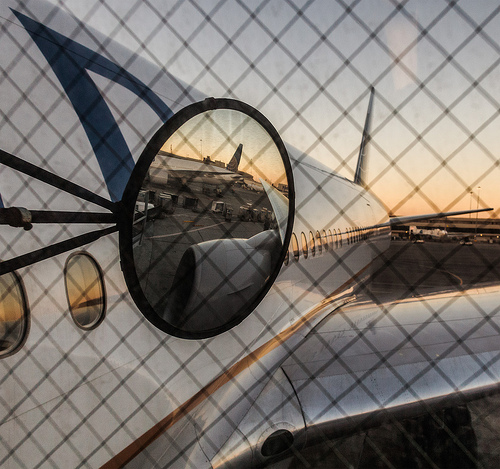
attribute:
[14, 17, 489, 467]
plane — parked, white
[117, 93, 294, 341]
side view mirror — round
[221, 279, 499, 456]
wing — large, white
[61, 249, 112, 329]
window — little, round, oval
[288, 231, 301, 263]
window — little, oval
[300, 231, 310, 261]
window — oval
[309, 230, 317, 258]
window — oval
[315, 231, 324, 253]
window — oval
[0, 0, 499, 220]
sky — sunny, bright, blue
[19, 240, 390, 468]
stripe — gold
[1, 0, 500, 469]
fence — gray